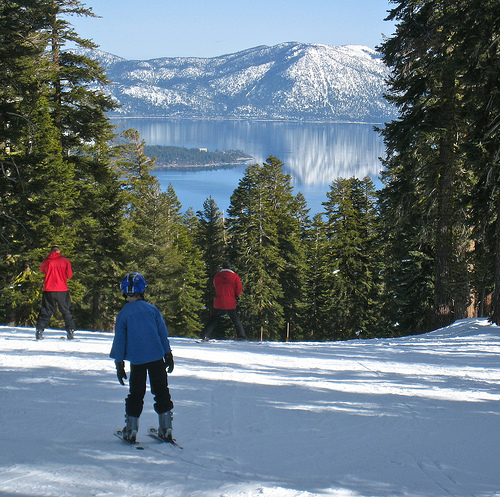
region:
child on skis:
[101, 268, 211, 464]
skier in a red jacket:
[186, 264, 276, 359]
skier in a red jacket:
[28, 241, 98, 371]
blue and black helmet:
[116, 263, 150, 300]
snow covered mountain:
[217, 31, 377, 129]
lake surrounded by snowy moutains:
[120, 108, 427, 219]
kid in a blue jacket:
[88, 243, 215, 484]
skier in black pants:
[32, 233, 103, 358]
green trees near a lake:
[269, 168, 428, 333]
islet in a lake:
[150, 136, 259, 175]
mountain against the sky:
[93, 22, 378, 85]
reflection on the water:
[286, 140, 365, 175]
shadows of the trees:
[231, 375, 451, 405]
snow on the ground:
[246, 340, 301, 370]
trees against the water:
[181, 147, 366, 217]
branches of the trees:
[311, 276, 396, 341]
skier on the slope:
[75, 256, 165, 481]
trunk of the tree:
[277, 312, 297, 357]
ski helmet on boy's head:
[105, 260, 165, 300]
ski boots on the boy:
[97, 395, 183, 452]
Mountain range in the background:
[64, 21, 413, 131]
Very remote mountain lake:
[85, 85, 418, 225]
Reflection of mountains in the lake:
[121, 113, 397, 180]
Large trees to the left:
[0, 2, 177, 356]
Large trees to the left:
[376, 10, 498, 345]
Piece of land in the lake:
[98, 130, 276, 190]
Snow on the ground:
[0, 307, 493, 495]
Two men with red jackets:
[23, 240, 272, 338]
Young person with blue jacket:
[85, 265, 202, 457]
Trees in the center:
[110, 145, 416, 351]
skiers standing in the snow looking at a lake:
[0, 10, 497, 492]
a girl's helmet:
[120, 271, 144, 295]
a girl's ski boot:
[122, 416, 140, 441]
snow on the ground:
[231, 347, 476, 480]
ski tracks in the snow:
[174, 448, 260, 483]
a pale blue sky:
[95, 8, 371, 38]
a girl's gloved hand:
[114, 362, 129, 387]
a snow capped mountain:
[224, 40, 384, 119]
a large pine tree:
[388, 3, 498, 320]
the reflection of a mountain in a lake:
[228, 117, 381, 156]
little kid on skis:
[96, 264, 199, 474]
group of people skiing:
[21, 231, 298, 461]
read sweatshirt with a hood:
[33, 245, 78, 292]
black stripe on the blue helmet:
[124, 272, 137, 292]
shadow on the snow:
[245, 416, 386, 468]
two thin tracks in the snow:
[409, 444, 459, 494]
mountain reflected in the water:
[253, 126, 373, 188]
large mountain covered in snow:
[114, 42, 399, 128]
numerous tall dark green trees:
[4, 8, 497, 329]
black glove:
[111, 361, 128, 385]